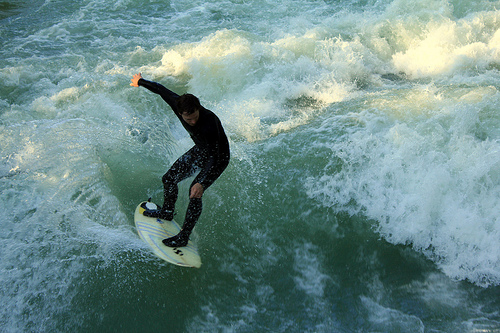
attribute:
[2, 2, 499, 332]
ocean — grey, rough, sunny, wavy, choppy, present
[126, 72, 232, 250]
man — standing, surfing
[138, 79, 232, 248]
wetsuit — black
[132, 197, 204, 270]
surfboard — striped, large, yellow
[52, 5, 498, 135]
wave — bright, white, crashing